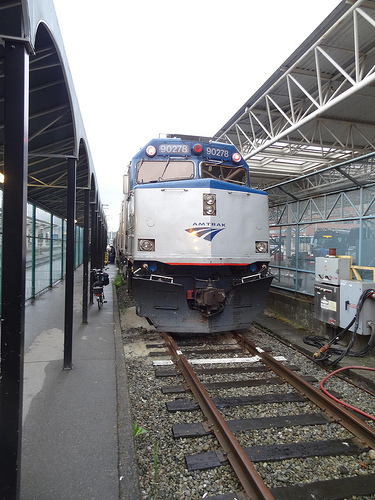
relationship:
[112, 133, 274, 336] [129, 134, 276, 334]
train has front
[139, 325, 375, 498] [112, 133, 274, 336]
tracks under train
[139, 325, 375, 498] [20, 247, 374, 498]
tracks on ground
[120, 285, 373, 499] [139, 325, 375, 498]
rocks on tracks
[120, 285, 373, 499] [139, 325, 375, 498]
rocks next to tracks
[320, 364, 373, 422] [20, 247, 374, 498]
hose laying on ground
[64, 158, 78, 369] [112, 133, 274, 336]
pole next to train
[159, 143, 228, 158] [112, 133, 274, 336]
number on train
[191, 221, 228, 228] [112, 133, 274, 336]
word on train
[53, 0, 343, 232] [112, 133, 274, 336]
sky above train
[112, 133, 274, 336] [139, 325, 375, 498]
train on tracks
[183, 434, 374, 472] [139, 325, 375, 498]
tie on tracks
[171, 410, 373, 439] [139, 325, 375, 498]
tie on tracks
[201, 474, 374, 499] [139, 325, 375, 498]
tie on tracks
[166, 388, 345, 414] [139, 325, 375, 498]
tie on tracks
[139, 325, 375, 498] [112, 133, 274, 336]
tracks for train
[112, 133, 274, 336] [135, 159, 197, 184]
train has window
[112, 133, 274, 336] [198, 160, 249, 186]
train has window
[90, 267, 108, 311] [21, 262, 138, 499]
bicycle on platform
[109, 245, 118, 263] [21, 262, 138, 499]
passenger on platform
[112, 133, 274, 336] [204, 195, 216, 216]
train has headlight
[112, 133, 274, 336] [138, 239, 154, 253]
train has headlight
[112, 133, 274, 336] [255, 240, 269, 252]
train has headlight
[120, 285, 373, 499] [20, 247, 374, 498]
rocks laying on ground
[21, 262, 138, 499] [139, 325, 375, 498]
cement next to tracks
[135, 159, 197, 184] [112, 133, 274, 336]
window on train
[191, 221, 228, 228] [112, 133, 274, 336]
word on front of train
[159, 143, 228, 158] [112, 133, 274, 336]
number printed on train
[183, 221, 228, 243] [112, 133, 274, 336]
logo on train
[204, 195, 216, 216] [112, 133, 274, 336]
headlight on train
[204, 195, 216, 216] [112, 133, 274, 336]
headlight on front of train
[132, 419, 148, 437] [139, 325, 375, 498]
plant growing on tracks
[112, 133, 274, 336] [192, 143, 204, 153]
train has light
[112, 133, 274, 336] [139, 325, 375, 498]
train on a tracks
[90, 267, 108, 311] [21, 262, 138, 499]
bicycle parked on platform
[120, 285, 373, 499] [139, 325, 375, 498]
rocks surrounding tracks